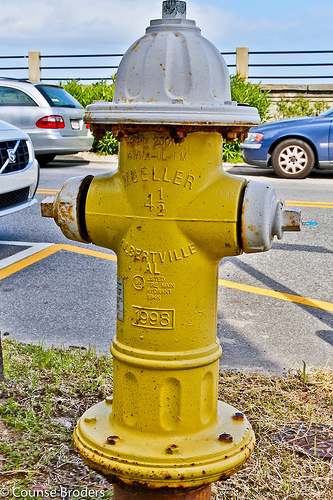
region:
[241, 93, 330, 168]
Front of blue car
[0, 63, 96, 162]
Back of silver station wagon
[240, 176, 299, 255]
Right side outlet of fire hydrant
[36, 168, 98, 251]
Left side outlet of fire hydrant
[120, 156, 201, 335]
Details marked on fire hydrant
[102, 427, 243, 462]
Bolts holding hydrant to base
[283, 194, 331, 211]
Yellow double lines in road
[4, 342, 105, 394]
Green grass coming through the brown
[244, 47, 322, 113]
Wall with additional barrier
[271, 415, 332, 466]
Metal plate covered by grass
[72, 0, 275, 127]
Top cap of a fire hydrant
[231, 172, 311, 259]
Side cap on a fire hydrant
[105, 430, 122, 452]
Bolt securing fire hydrant to pipe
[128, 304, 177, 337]
Date of manufacture stamped in fire hydrant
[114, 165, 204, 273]
Name of the manufacturer stamped in a fire hydrant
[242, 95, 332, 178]
Car parked on the street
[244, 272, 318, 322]
Yellow lines painted on the road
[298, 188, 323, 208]
Double yellow lines painted on the road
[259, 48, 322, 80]
Safety railing for sidewalk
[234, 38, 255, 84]
Support post for safety railing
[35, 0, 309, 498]
a yellow fire hydrant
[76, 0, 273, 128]
top part of hydrant is white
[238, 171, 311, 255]
right side of hydrant is white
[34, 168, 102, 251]
left side of hydrant is white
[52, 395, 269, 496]
base of hydrant is rusty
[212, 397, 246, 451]
bolts are rusty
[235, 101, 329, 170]
blue car park on side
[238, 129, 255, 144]
headlight in front of car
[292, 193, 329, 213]
two yellow lines in center of street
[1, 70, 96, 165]
a tan car with back red lights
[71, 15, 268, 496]
this is a hydrant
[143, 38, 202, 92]
the lid is white in color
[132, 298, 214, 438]
the hydrant is metallic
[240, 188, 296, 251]
the hydrant is rusty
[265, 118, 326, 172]
this is a car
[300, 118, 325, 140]
the car is blue in color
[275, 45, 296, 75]
this is a fence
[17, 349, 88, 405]
the grass are short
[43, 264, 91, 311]
the road is tarmacked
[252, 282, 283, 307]
the strip is yellow in color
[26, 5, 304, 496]
Yellow rusted fire hydrant.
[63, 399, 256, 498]
Base of yellow rusted fire hydrant.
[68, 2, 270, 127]
Top of yellow rusted fire hydrant.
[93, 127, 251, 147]
Screws and bolts under fire hydrant top.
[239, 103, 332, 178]
Blue car parked across street in parking space.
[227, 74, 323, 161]
Shrubbery growing on side of street next to blue car.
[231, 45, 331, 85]
Fence on top of concrete retaining wall.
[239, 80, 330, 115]
Concrete retainging wall next to shrubbery.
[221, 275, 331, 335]
Yellow line on street indicates no parking in front of fire hydrant.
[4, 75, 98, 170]
Rear of gray car parked in parking space across street.